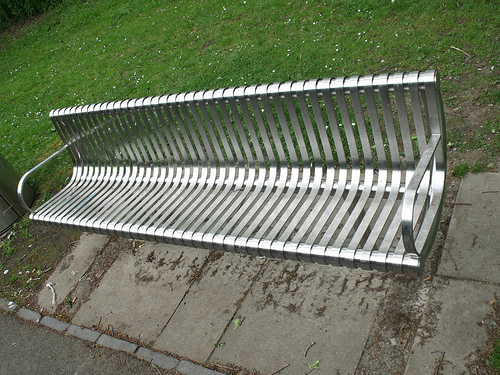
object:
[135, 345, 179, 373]
brick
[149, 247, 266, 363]
concrete panels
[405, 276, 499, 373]
concrete panels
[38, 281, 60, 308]
garbage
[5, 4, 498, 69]
grass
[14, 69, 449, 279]
silver bench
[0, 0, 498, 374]
park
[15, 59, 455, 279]
metal bench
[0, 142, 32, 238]
container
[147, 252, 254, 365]
panels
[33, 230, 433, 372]
pavers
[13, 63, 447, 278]
seat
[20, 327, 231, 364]
concrete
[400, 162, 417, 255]
metal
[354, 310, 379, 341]
line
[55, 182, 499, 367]
slabs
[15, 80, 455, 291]
bench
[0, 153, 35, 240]
trash can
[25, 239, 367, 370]
cement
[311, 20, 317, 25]
flower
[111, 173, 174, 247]
metal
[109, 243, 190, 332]
blocks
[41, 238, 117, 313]
concrete line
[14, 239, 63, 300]
leaves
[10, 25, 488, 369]
patio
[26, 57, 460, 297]
slats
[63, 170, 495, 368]
platform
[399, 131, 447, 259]
arm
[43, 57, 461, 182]
back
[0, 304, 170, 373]
pavement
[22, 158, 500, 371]
pad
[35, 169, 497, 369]
concrete pad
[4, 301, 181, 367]
road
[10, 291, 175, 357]
trim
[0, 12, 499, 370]
pavers